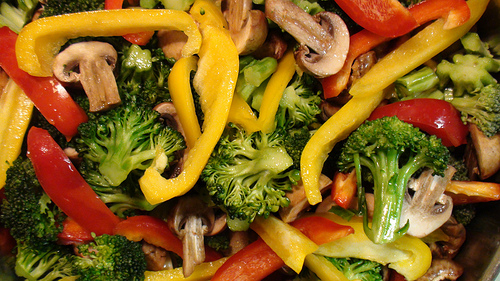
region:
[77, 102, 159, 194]
the broccoli is green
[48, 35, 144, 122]
the mushroom is brown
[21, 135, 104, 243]
the pepper is red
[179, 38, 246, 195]
the pepper is yellow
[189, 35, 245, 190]
the pepper is chopped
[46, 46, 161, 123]
the mushroom is chopped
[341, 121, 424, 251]
broccoli is looks like a tree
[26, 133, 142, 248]
the bell pepper is long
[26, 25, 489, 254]
the vegetables are sauted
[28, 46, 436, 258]
the veggies are steamed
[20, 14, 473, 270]
chopped vegetables with oil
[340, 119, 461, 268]
chopped broccli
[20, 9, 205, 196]
sliced yellow pepper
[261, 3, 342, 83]
sliced mushrooms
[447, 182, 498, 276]
corner of frying pan or wok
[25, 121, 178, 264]
pieces of sliced red pepper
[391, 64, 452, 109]
chopped broccoli stalk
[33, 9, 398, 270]
sliced vegetables are ready to cook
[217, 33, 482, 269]
sliced vegetables are part of a Chinese dish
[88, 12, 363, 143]
sliced vegetables are going into soup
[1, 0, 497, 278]
Food is a stir fry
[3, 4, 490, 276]
There are yellow peppers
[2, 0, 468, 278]
There are red peppers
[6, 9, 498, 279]
The broccoli is green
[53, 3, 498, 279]
Mushrooms are mixed in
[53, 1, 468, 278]
Mushrooms are white and brown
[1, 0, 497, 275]
Cooked vegetables are glistening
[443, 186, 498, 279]
Edge of bowl is showing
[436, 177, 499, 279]
The bowl is metal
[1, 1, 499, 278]
Everything is mixed together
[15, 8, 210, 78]
Freshly sliced yellow peppers.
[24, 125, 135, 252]
Freshly sliced red peppers.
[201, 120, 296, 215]
Freshly separated broccoli florets.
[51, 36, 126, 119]
Freshly sliced button mushrooms.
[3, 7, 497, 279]
A medley of fresh vegetables.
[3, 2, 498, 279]
The fixings of a stir fry dish.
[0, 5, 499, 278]
Lightly sauteed summer vegetables.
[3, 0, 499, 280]
Olive oil over mixed vegetables.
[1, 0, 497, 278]
Fast and fresh way to cook.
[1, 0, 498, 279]
Quick and easy stir fry dish.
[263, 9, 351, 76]
An evenly sliced mushroom.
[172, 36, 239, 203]
A strip of sliced yellow bell pepper.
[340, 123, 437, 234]
A floret of broccoli.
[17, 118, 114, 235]
A strip of red bell pepper.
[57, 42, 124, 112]
A sliced mushroom among peppers and broccoli.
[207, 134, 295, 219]
A piece of broccoli.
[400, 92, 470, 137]
A red bell pepper chunk.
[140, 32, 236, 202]
Yellow bell pepper slices.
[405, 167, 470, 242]
An upside down sliced mushroom.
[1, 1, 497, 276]
A salad blend of sliced mushrooms, broccoli, and strips of red and yellow bell peppers.